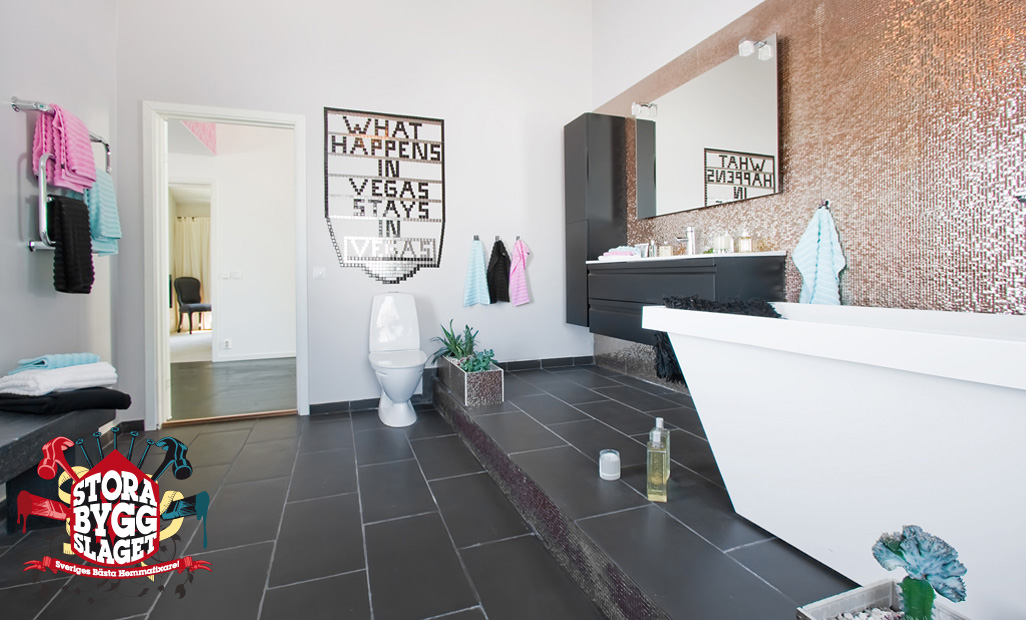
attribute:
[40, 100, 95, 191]
towel — black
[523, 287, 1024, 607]
bathtub — square, white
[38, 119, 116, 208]
towel — pink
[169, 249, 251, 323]
chair — black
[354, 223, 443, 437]
toilet — white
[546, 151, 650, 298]
cabinet — black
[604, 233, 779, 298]
vanity — black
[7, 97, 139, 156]
towel — pink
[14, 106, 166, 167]
towel — black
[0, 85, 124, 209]
towel — blue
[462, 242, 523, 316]
hand towel — pink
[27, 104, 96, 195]
towel — large, purple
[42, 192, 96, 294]
towel — large, black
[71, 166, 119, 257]
towel — large, blue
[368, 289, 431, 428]
toilet — small, white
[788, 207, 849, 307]
towel — large, blue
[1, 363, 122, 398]
towel — large, white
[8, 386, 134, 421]
towel — large, black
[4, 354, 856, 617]
floor — black, tiled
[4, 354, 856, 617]
lines — white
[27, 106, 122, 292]
towels — pink, black, blue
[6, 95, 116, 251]
rack — metal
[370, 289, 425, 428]
toilet — white, porcelain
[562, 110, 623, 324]
cabinet — black, shiny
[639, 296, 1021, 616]
bath tub — large, white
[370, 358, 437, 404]
bowl — white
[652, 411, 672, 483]
bottle — clear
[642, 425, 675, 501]
bottle — clear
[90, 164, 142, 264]
towel — blue, hand 